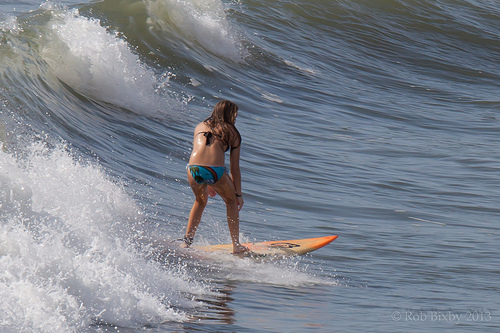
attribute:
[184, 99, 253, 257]
woman — surfing, hunched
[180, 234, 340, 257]
surfboard — orange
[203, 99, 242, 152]
hair — brown, long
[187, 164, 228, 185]
bottoms — blue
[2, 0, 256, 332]
wave — cresting, yellow, splashing, big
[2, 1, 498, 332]
water — ocean, green, shiny, calm, choppy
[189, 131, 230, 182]
bikini — blue, black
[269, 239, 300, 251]
design — black